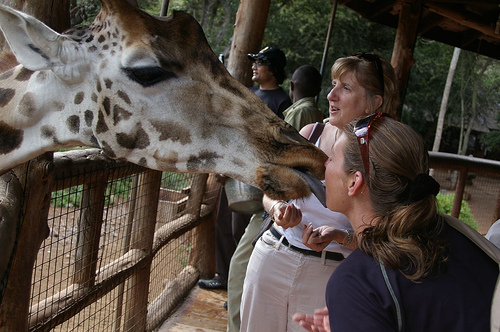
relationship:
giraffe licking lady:
[2, 1, 327, 203] [293, 111, 498, 331]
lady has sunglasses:
[293, 111, 498, 331] [354, 112, 388, 187]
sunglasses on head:
[354, 112, 388, 187] [323, 116, 432, 213]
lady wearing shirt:
[293, 111, 498, 331] [326, 219, 498, 331]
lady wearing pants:
[238, 50, 395, 331] [240, 223, 347, 331]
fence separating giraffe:
[2, 147, 223, 332] [2, 1, 327, 203]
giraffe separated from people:
[2, 1, 327, 203] [198, 46, 496, 330]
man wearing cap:
[196, 46, 286, 291] [248, 44, 288, 69]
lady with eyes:
[293, 111, 498, 331] [326, 152, 337, 165]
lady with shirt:
[293, 111, 498, 331] [326, 219, 498, 331]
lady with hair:
[293, 111, 498, 331] [345, 116, 450, 287]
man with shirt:
[196, 46, 286, 291] [253, 89, 294, 121]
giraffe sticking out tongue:
[2, 1, 327, 203] [296, 169, 328, 208]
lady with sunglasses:
[293, 111, 498, 331] [354, 112, 388, 187]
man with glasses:
[196, 46, 286, 291] [250, 60, 266, 66]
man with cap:
[196, 46, 286, 291] [248, 44, 288, 69]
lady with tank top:
[238, 50, 395, 331] [274, 120, 359, 255]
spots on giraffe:
[1, 15, 217, 177] [2, 1, 327, 203]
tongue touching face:
[296, 169, 328, 208] [325, 132, 348, 215]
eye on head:
[120, 62, 177, 89] [51, 2, 329, 201]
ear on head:
[1, 3, 67, 74] [51, 2, 329, 201]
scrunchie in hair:
[409, 171, 442, 201] [345, 116, 450, 287]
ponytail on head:
[356, 183, 451, 284] [323, 116, 432, 213]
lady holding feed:
[238, 50, 395, 331] [281, 203, 331, 237]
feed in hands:
[281, 203, 331, 237] [266, 197, 340, 253]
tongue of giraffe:
[296, 169, 328, 208] [2, 1, 327, 203]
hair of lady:
[345, 116, 450, 287] [293, 111, 498, 331]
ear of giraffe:
[1, 3, 67, 74] [2, 1, 327, 203]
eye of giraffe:
[120, 62, 177, 89] [2, 1, 327, 203]